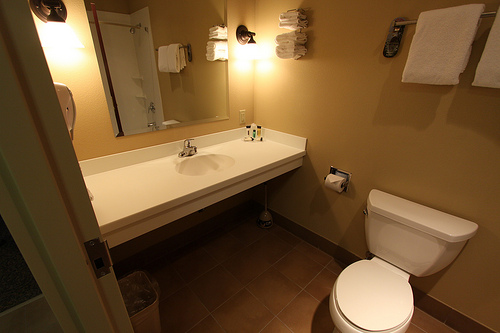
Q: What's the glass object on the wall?
A: A mirror.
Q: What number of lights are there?
A: Two.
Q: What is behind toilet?
A: Tan color wall.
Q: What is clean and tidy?
A: Restroom.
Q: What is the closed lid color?
A: White.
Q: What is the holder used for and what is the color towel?
A: Towel and white.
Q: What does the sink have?
A: Large mirror.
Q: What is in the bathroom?
A: White toilet.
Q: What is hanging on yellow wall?
A: Bathroom mirror.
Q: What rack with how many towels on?
A: One rack with two white towel.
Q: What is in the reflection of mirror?
A: Shower.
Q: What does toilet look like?
A: White and clean.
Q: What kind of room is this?
A: Bathroom.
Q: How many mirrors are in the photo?
A: One.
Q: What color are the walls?
A: Yellow.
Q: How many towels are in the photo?
A: Nine.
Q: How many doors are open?
A: One.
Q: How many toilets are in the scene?
A: One.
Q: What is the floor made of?
A: Tiles.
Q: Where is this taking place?
A: In a house.